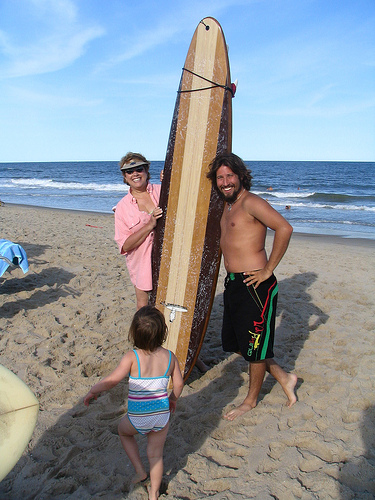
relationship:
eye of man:
[210, 163, 224, 178] [187, 111, 316, 399]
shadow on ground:
[299, 290, 336, 323] [264, 258, 366, 368]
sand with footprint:
[30, 264, 124, 363] [85, 290, 103, 342]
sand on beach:
[30, 264, 124, 363] [5, 268, 118, 344]